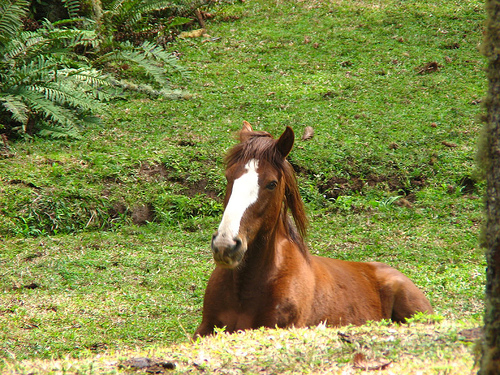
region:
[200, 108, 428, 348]
brown and white horse in the grass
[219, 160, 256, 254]
white spot on the horse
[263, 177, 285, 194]
eye on the horse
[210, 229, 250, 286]
nose on the horse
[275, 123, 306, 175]
ear on the horse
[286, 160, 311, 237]
mane on the horse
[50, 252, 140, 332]
grass on the ground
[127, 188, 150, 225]
bare spot in the grass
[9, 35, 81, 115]
ferns next to the grass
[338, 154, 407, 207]
bare spot in the grass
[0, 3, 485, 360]
green grass on ground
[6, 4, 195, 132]
green leaves on plant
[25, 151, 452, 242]
long ditch in ground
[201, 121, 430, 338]
reclined horse on grass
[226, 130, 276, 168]
mane on horse head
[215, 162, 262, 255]
white patch on horse head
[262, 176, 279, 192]
eye on horse head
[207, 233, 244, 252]
nostrils on horse nose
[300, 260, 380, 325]
torso on horse body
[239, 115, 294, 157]
ears on horse head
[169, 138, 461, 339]
a horse sitting in the grass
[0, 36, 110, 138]
a fern in the background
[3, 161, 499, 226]
a ditch behind the horse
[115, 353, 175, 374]
a black rock in front of the horse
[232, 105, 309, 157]
the horses ears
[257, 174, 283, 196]
the horses left eye ball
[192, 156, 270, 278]
the horses snout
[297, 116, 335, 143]
a gray rock behind the horse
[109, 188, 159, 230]
a brown piece of mud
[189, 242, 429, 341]
the horses torso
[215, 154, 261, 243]
the horse has a white on its face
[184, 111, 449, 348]
the horse is laying down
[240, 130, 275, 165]
the horses mane is brown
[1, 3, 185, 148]
the fern plant is green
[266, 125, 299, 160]
the horses ears are perked up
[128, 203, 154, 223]
mud on the side of the gully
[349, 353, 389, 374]
a brown leaf on the ground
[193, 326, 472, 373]
the sun is casting shadows in front of the horse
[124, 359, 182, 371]
horse manure in the grass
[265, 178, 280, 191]
the horses eye is brown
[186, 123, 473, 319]
horse laying grassy field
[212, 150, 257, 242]
white marking on horse's face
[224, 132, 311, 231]
brown hair of horse's man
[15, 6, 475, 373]
grassy area horse is laying in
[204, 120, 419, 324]
brown horse with white face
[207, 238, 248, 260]
nostrils of brown horse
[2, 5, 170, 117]
ferns growing along grassy hillside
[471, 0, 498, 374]
tree trunk in foreground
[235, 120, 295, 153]
ears of brown horse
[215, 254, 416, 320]
body of brown horse